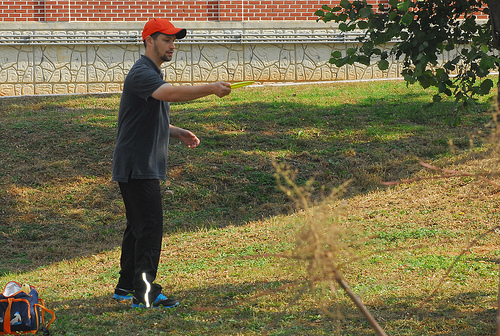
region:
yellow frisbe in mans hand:
[214, 80, 256, 93]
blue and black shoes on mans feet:
[128, 288, 179, 310]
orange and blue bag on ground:
[4, 282, 56, 309]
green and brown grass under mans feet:
[97, 224, 274, 319]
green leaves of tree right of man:
[319, 4, 498, 106]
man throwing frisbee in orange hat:
[114, 20, 260, 170]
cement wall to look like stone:
[246, 42, 298, 82]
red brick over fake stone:
[249, 2, 306, 80]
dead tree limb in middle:
[315, 204, 386, 329]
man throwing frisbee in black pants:
[110, 18, 253, 304]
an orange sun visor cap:
[142, 15, 188, 40]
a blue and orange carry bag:
[0, 289, 55, 334]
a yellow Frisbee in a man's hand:
[210, 77, 257, 99]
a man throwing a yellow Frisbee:
[112, 16, 255, 313]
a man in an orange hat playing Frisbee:
[57, 8, 313, 334]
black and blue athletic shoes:
[111, 284, 181, 309]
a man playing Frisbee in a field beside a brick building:
[9, 5, 491, 331]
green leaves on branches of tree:
[314, 0, 498, 116]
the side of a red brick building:
[2, 3, 117, 98]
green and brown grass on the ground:
[250, 88, 384, 146]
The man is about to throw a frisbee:
[209, 65, 305, 116]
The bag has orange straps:
[11, 275, 57, 332]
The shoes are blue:
[95, 289, 177, 321]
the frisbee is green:
[230, 75, 257, 92]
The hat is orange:
[145, 13, 189, 38]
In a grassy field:
[57, 110, 424, 306]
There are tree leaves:
[307, 9, 476, 102]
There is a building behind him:
[0, 25, 408, 123]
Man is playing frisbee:
[77, 33, 254, 307]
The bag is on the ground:
[0, 276, 65, 334]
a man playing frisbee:
[110, 15, 257, 308]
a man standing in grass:
[109, 18, 232, 304]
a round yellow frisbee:
[229, 78, 256, 89]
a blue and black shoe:
[130, 292, 177, 308]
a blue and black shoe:
[109, 283, 129, 297]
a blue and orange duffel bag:
[2, 279, 55, 334]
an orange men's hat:
[142, 18, 186, 41]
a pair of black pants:
[114, 178, 163, 303]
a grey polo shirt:
[109, 53, 171, 183]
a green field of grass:
[0, 73, 499, 332]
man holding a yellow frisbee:
[195, 60, 250, 118]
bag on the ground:
[2, 259, 77, 334]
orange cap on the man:
[122, 6, 184, 93]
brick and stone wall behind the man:
[37, 0, 115, 87]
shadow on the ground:
[262, 86, 422, 136]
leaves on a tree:
[334, 9, 479, 111]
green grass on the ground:
[381, 224, 449, 254]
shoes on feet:
[106, 269, 195, 321]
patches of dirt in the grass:
[11, 125, 90, 189]